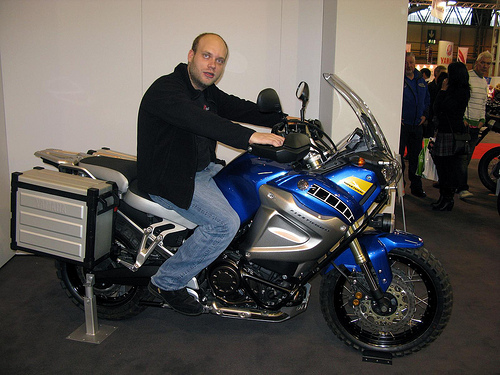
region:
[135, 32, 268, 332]
a man on a blue and silver motorcycle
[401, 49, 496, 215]
people at an exhibition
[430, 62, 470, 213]
a woman in dark clothes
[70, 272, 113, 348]
a silver stand supporting motorcycle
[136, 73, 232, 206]
a black jacket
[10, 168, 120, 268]
a silver saddle box on motorcylce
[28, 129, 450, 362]
blue and silver motorcycle at an exhibition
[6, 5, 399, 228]
a wall behind motorcycle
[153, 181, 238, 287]
blue jeans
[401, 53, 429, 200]
man in blue jacket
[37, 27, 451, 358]
man sitting on blue and silver motorcycle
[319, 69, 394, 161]
clear visor on bike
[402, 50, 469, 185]
people standing in showroom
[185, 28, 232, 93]
man with balding head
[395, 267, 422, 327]
chrome spokes on wheel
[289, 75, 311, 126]
side view mirror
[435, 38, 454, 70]
Yamaha banner hanging from ceiling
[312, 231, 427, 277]
front blue fender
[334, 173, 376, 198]
yellow box with black writing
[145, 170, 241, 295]
faded blue denim jeans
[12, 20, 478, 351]
man sitting on a motorcycle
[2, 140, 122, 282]
sidebag for motorcycle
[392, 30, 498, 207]
guests at a motorcycle show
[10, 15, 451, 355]
blue motorcycle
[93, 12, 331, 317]
man wearing blue jeans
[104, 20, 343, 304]
man wearing a sports jacket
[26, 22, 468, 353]
demo motorcycle at a show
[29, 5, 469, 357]
blue and silver motorcycle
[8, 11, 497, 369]
motorcycle showcase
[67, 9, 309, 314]
man at motorcycle show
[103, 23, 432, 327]
man sitting on motorcycle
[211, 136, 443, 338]
motorcycle is blue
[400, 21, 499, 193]
a crowd is milling just outside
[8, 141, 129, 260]
silver carrying cases are mounted on the back of the bike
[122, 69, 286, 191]
the man is wearing a black jacket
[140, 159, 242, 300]
the man is wearing blue jeans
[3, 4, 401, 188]
a beige wall is behind the man on the motorcycle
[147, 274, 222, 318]
the man is wearing black shoes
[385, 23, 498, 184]
people standing around at an event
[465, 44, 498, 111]
a man is looking toward the man on the bike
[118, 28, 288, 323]
man on a motorcycle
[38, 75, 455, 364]
blue and silver motorcycle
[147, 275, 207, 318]
man's black shoe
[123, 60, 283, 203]
man's dark colored jacket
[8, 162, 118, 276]
silver colored box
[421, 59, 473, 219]
woman with a skirt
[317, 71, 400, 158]
clear windshield on a bike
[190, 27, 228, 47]
man's bald head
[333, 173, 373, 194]
yellow sticker on a bike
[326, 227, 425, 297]
blue fender on a bike